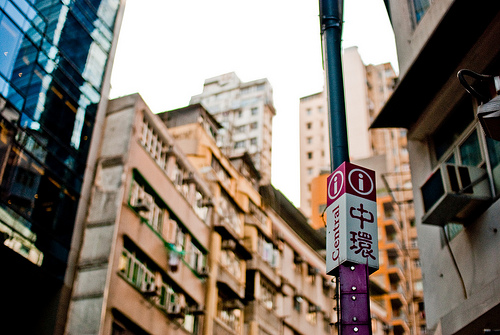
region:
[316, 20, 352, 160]
The pole is black.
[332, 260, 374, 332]
The pole is fuschia colored.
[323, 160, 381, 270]
A white and fuschia sign on the pole.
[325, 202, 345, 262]
The sign says central on it.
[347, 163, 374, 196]
A white circle with an i inside of it.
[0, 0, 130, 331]
The tall building has many glass windows.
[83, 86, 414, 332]
The building is brown.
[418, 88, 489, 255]
A window on a building.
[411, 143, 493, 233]
An air conditioning unit in the window.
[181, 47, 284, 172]
A high rise building in the distance.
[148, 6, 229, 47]
this is the sky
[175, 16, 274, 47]
the sky is full of clouds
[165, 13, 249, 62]
the clouds are white in color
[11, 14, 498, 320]
these are some buildings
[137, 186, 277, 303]
the building has several windows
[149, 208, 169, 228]
the windows are closed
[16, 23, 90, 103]
the windows are shiny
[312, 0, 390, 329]
this is a pole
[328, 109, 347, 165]
the pole is metallic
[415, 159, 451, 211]
this is a chimney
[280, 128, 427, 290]
a street sign in china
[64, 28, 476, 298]
shot of an asian street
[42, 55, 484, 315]
the angle is looking up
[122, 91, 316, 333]
an apartment complex in background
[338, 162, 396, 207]
the information symbol on sign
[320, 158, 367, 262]
the word in english is central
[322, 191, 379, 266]
this text is red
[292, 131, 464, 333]
the sign is red and white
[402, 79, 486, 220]
an air conditioning machine in window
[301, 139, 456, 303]
one side is in english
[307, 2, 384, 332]
a street sign surrounded by buildings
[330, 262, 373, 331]
the sign bottom is pink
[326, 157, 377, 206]
an information symbol on the sign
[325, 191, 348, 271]
this sign is in English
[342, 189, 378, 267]
this sign has other characters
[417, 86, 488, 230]
an air conditioning unit sticking out the window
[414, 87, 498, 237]
a window on a building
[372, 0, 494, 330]
a building beside the sign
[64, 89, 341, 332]
a building across the street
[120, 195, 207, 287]
a green strip on the building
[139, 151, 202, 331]
the building has several windows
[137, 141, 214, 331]
the windows are many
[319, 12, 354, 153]
this is a pole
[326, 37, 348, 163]
the pole is metallic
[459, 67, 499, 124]
this is a light